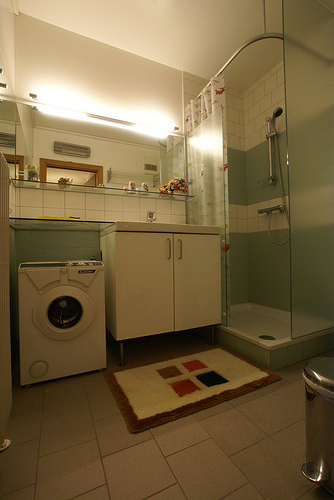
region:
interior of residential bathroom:
[4, 2, 331, 491]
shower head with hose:
[270, 104, 292, 246]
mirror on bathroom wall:
[9, 10, 185, 219]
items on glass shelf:
[11, 170, 193, 201]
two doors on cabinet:
[113, 221, 221, 338]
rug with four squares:
[104, 345, 281, 435]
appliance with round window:
[17, 257, 108, 384]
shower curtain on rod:
[185, 73, 228, 309]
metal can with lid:
[301, 355, 332, 492]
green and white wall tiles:
[183, 67, 289, 303]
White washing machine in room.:
[28, 274, 101, 361]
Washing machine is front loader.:
[27, 282, 88, 345]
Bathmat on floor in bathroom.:
[114, 356, 240, 412]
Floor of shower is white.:
[244, 307, 284, 345]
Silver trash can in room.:
[303, 396, 322, 497]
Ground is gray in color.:
[55, 413, 116, 480]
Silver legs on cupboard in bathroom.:
[116, 345, 132, 361]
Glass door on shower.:
[297, 296, 331, 324]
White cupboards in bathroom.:
[149, 265, 196, 304]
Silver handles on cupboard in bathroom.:
[165, 232, 190, 258]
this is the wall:
[90, 53, 140, 106]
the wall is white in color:
[82, 53, 112, 100]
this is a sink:
[235, 293, 282, 341]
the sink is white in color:
[246, 302, 283, 324]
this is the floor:
[195, 433, 280, 488]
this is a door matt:
[150, 349, 222, 414]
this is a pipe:
[270, 126, 280, 201]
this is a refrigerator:
[111, 213, 164, 325]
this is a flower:
[161, 172, 191, 198]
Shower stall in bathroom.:
[219, 75, 320, 370]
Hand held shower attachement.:
[255, 101, 284, 188]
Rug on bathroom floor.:
[102, 345, 287, 435]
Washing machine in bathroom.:
[15, 252, 111, 387]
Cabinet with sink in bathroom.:
[99, 216, 221, 350]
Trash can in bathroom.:
[295, 354, 332, 498]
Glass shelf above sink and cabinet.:
[10, 172, 192, 205]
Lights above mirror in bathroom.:
[34, 78, 181, 142]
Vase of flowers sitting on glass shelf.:
[163, 174, 190, 198]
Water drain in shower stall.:
[257, 328, 277, 343]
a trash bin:
[299, 353, 332, 498]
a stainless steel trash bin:
[296, 352, 333, 498]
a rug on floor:
[100, 340, 284, 436]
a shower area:
[181, 29, 333, 364]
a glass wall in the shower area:
[180, 104, 229, 327]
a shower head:
[271, 105, 283, 117]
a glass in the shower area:
[281, 0, 331, 340]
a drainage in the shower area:
[255, 332, 276, 340]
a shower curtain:
[185, 73, 230, 323]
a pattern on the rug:
[155, 355, 230, 399]